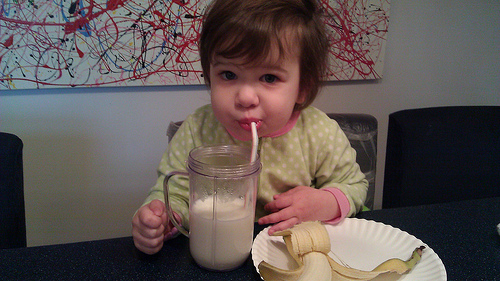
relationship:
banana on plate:
[291, 243, 337, 278] [367, 219, 396, 250]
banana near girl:
[291, 243, 337, 278] [188, 14, 318, 167]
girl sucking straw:
[188, 14, 318, 167] [237, 113, 274, 155]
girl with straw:
[188, 14, 318, 167] [237, 113, 274, 155]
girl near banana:
[188, 14, 318, 167] [291, 243, 337, 278]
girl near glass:
[188, 14, 318, 167] [174, 142, 273, 256]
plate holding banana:
[367, 219, 396, 250] [291, 243, 337, 278]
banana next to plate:
[291, 243, 337, 278] [367, 219, 396, 250]